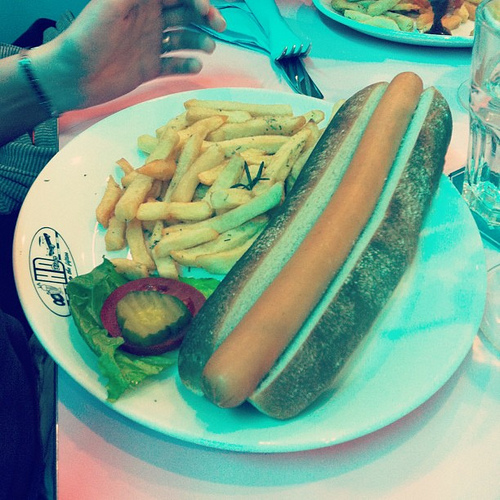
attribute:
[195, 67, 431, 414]
hotdog — cooked, large, long, red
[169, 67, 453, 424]
bun — burnt looking, brown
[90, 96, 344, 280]
french fries — seasoned, brown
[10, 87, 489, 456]
plate — white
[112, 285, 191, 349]
pickle — sliced, green, yellow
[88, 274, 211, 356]
tomato — sliced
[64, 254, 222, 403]
lettuce — green, sliced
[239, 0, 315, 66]
fork — silver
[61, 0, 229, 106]
hand — of person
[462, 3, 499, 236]
glass — clear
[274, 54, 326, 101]
knife — silver, metal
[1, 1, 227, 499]
person — sitting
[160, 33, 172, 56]
wedding band — metal